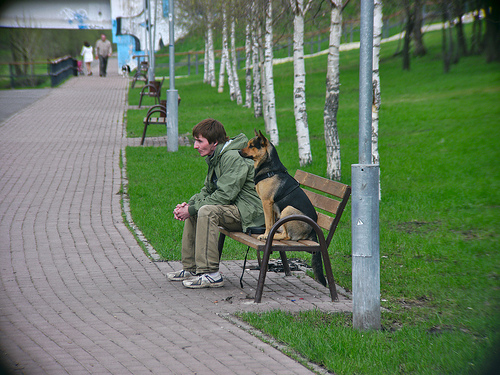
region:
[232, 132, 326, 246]
this is a dog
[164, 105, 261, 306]
this is a person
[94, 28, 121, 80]
this is a person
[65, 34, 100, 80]
this is a person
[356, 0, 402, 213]
the bark of a tree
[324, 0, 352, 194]
the bark of a tree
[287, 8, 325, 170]
the bark of a tree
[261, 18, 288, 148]
the bark of a tree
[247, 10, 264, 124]
the bark of a tree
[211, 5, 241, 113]
the bark of a tree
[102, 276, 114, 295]
brick on the sidewalk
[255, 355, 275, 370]
brick on the sidewalk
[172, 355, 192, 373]
brick on the sidewalk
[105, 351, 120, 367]
brick on the sidewalk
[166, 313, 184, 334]
brick on the sidewalk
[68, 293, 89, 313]
brick on the sidewalk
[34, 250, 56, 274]
brick on the sidewalk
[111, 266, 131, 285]
brick on the sidewalk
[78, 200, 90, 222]
brick on the sidewalk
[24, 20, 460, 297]
a man and dog in a park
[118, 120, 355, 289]
this man and dog are sitting on a bench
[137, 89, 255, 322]
the man has on a green coat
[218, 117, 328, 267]
the dog is watching something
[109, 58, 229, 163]
the bench is brown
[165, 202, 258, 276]
the man is wearing brown pants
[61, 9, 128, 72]
people in the background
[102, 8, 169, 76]
a blue and white building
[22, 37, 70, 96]
a rail on a bridge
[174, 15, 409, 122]
trees in the area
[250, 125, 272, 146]
A guid dogs ears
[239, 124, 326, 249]
Dog sitting on bench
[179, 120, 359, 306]
Man and dog sitting together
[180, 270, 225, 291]
A white running shoe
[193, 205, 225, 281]
Brown running pants leg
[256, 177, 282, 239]
A dogs front arm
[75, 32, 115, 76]
Two people in the distance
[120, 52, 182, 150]
A row of benches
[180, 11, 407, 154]
A row of white trees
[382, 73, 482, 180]
The side of a hill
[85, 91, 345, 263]
This is a picture of a man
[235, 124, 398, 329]
This is a picture of a dog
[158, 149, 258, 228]
The man is sitting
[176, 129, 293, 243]
This is a green jacket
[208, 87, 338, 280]
This is a picture of a dog sitting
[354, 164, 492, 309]
This is a metal pole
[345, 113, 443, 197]
The pole is silver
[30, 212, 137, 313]
This is a cobblestone path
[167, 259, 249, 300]
These are white sneakers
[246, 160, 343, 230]
The dog is brown and black